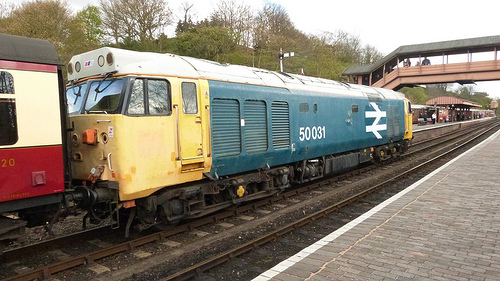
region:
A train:
[81, 87, 188, 198]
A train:
[88, 51, 262, 209]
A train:
[165, 137, 275, 279]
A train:
[167, 102, 347, 276]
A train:
[127, 82, 278, 269]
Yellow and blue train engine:
[57, 38, 412, 225]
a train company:
[361, 96, 391, 146]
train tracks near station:
[1, 119, 498, 278]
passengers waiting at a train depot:
[425, 96, 494, 135]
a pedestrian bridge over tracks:
[332, 31, 499, 90]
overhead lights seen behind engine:
[264, 36, 311, 73]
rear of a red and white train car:
[2, 45, 69, 222]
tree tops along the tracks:
[5, 0, 364, 86]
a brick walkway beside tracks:
[277, 136, 496, 278]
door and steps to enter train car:
[173, 63, 215, 219]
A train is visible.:
[192, 66, 311, 172]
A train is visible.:
[121, 108, 256, 227]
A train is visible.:
[174, 96, 279, 205]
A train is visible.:
[155, 102, 241, 174]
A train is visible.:
[136, 27, 275, 172]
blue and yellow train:
[67, 35, 419, 179]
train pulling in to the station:
[10, 22, 437, 207]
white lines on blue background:
[363, 96, 393, 143]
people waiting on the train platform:
[415, 91, 497, 123]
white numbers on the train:
[296, 122, 333, 146]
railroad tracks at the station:
[130, 232, 255, 265]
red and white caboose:
[6, 30, 75, 220]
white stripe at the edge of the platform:
[303, 216, 375, 246]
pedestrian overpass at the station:
[340, 30, 499, 93]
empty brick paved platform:
[403, 196, 473, 258]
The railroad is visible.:
[168, 194, 279, 276]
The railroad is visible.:
[261, 172, 389, 260]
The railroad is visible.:
[205, 200, 367, 275]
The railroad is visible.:
[197, 167, 317, 244]